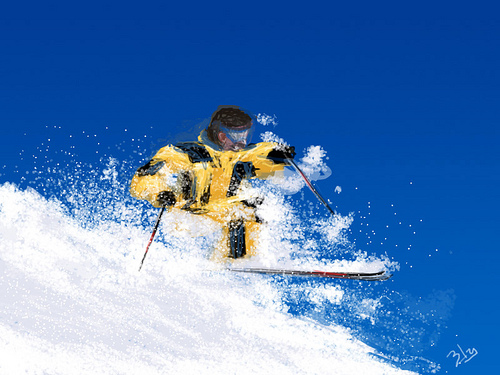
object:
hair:
[206, 104, 253, 139]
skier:
[126, 105, 392, 283]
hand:
[156, 190, 176, 206]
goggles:
[217, 123, 250, 143]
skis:
[172, 262, 394, 281]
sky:
[4, 3, 472, 100]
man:
[129, 87, 299, 296]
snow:
[48, 299, 118, 374]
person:
[129, 104, 386, 284]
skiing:
[138, 171, 388, 299]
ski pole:
[282, 147, 339, 219]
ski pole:
[132, 200, 166, 271]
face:
[223, 125, 252, 153]